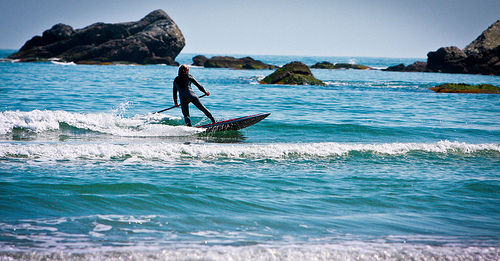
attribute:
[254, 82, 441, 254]
water — bright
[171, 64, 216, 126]
person — surfing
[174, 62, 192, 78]
hair — blonde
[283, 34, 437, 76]
island — grassy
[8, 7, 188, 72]
rock — big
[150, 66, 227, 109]
woman — blond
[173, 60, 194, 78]
hair — long